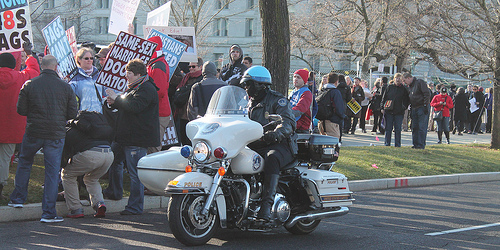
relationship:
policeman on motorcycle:
[239, 64, 298, 218] [135, 86, 355, 245]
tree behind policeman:
[260, 0, 290, 97] [239, 64, 298, 218]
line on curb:
[394, 179, 399, 189] [346, 170, 499, 194]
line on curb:
[399, 179, 406, 187] [346, 170, 499, 194]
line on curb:
[404, 177, 409, 186] [346, 170, 499, 194]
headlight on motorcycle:
[192, 141, 214, 157] [135, 86, 355, 245]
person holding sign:
[2, 41, 42, 204] [0, 1, 34, 53]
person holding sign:
[67, 47, 109, 115] [39, 15, 80, 83]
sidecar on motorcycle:
[138, 145, 194, 197] [135, 86, 355, 245]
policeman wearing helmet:
[239, 64, 298, 218] [238, 64, 273, 85]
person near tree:
[286, 67, 313, 128] [260, 0, 290, 97]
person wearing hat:
[286, 67, 313, 128] [294, 68, 311, 84]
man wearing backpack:
[64, 124, 113, 219] [69, 112, 114, 142]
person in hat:
[286, 67, 313, 128] [294, 68, 311, 84]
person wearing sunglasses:
[67, 47, 109, 115] [83, 56, 93, 61]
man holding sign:
[350, 76, 364, 135] [346, 96, 362, 115]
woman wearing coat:
[430, 85, 454, 141] [431, 95, 455, 118]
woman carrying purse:
[430, 85, 454, 141] [431, 99, 447, 120]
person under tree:
[451, 87, 471, 136] [288, 1, 499, 147]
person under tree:
[469, 85, 484, 134] [288, 1, 499, 147]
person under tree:
[370, 77, 383, 133] [288, 1, 499, 147]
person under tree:
[361, 80, 373, 133] [288, 1, 499, 147]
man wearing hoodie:
[217, 44, 247, 83] [219, 43, 245, 85]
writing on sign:
[43, 19, 75, 79] [39, 15, 80, 83]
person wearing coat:
[16, 55, 79, 223] [15, 70, 81, 136]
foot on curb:
[6, 202, 23, 210] [2, 194, 174, 221]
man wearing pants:
[64, 124, 113, 219] [62, 148, 119, 208]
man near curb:
[64, 124, 113, 219] [2, 194, 174, 221]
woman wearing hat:
[430, 85, 454, 141] [440, 87, 448, 94]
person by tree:
[286, 67, 313, 128] [260, 0, 290, 97]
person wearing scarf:
[286, 67, 313, 128] [290, 87, 310, 110]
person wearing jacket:
[67, 47, 109, 115] [69, 67, 107, 114]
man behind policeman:
[217, 44, 247, 83] [239, 64, 298, 218]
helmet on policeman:
[238, 64, 273, 85] [239, 64, 298, 218]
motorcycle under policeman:
[135, 86, 355, 245] [239, 64, 298, 218]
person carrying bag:
[380, 72, 409, 146] [381, 100, 394, 110]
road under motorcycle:
[0, 182, 499, 248] [135, 86, 355, 245]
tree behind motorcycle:
[260, 0, 290, 97] [135, 86, 355, 245]